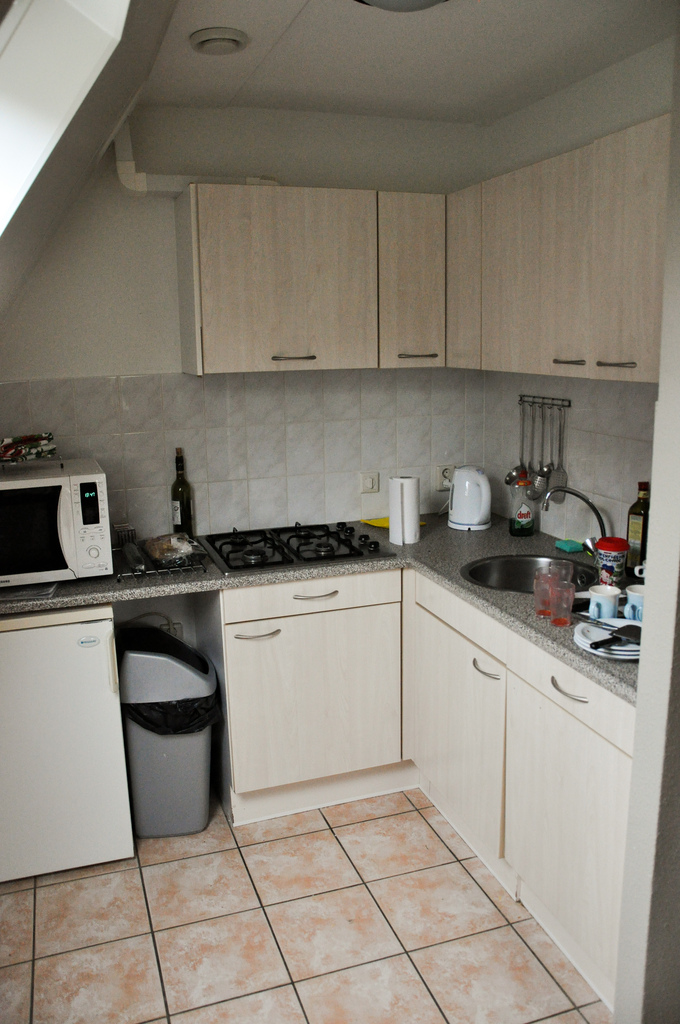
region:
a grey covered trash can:
[121, 625, 221, 839]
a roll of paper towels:
[389, 479, 423, 545]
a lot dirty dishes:
[536, 538, 642, 677]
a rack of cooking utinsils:
[504, 397, 576, 504]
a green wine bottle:
[171, 447, 192, 546]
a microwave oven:
[0, 460, 118, 586]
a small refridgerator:
[0, 616, 132, 888]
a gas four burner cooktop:
[202, 512, 398, 576]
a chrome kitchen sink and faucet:
[462, 489, 630, 595]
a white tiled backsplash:
[4, 383, 478, 537]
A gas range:
[184, 497, 396, 579]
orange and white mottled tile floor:
[0, 782, 618, 1021]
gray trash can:
[112, 616, 220, 838]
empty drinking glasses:
[530, 556, 577, 629]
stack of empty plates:
[575, 613, 643, 659]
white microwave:
[0, 459, 115, 589]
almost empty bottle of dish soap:
[506, 470, 542, 538]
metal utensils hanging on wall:
[504, 393, 570, 505]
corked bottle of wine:
[168, 442, 197, 540]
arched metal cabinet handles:
[265, 349, 640, 372]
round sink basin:
[459, 550, 600, 597]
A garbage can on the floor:
[59, 622, 259, 853]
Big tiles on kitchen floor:
[194, 867, 493, 1014]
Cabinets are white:
[248, 561, 618, 919]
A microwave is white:
[17, 431, 146, 601]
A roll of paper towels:
[351, 449, 444, 582]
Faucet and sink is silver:
[470, 483, 618, 637]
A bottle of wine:
[142, 434, 221, 562]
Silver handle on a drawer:
[272, 570, 356, 617]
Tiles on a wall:
[181, 382, 363, 505]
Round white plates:
[566, 594, 643, 679]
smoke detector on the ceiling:
[176, 19, 255, 55]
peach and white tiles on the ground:
[255, 869, 441, 975]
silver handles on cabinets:
[233, 623, 287, 642]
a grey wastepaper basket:
[140, 752, 194, 796]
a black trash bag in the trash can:
[157, 711, 205, 730]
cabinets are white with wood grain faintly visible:
[262, 677, 377, 756]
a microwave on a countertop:
[0, 465, 111, 587]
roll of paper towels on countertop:
[388, 470, 424, 550]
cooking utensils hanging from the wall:
[504, 390, 572, 501]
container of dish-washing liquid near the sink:
[508, 475, 538, 539]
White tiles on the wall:
[209, 400, 345, 506]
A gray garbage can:
[105, 618, 241, 866]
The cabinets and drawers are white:
[225, 576, 605, 920]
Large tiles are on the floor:
[137, 872, 507, 1010]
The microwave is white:
[6, 441, 136, 606]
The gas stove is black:
[204, 508, 387, 597]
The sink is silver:
[461, 507, 612, 622]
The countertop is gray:
[422, 533, 469, 571]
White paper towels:
[366, 458, 429, 561]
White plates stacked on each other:
[562, 603, 648, 685]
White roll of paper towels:
[370, 460, 442, 571]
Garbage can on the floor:
[86, 609, 251, 868]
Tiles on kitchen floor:
[242, 865, 457, 1011]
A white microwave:
[7, 448, 137, 615]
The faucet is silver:
[529, 462, 611, 570]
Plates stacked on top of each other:
[555, 602, 639, 681]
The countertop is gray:
[421, 531, 541, 646]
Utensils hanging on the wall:
[498, 398, 571, 523]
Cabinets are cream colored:
[169, 177, 602, 403]